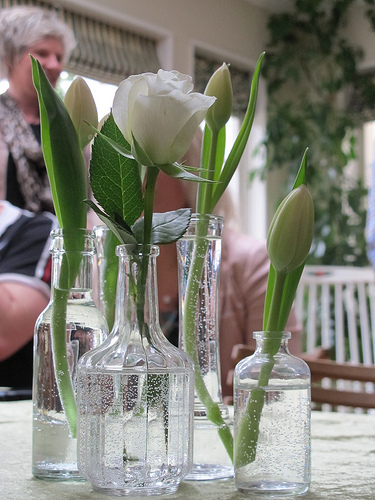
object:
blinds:
[102, 25, 114, 71]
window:
[67, 17, 164, 117]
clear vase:
[74, 241, 194, 494]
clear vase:
[174, 211, 234, 481]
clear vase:
[32, 228, 109, 481]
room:
[3, 3, 373, 500]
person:
[0, 6, 76, 204]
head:
[0, 5, 75, 91]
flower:
[263, 179, 316, 282]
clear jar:
[231, 329, 312, 498]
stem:
[133, 163, 159, 338]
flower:
[112, 65, 215, 168]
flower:
[201, 61, 234, 134]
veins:
[105, 160, 120, 174]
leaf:
[130, 207, 190, 242]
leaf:
[28, 54, 90, 277]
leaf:
[212, 56, 260, 207]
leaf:
[262, 147, 308, 358]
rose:
[62, 75, 97, 148]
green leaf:
[88, 104, 138, 225]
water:
[232, 380, 312, 491]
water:
[188, 367, 222, 402]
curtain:
[69, 18, 163, 77]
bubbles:
[270, 422, 273, 426]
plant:
[254, 1, 375, 366]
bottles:
[229, 328, 310, 496]